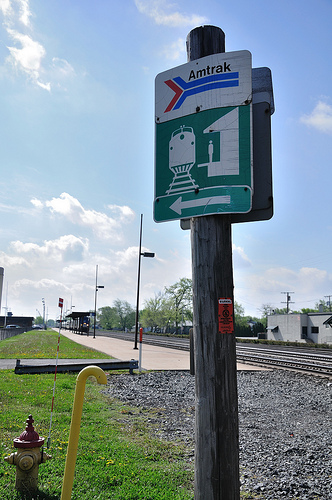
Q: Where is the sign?
A: On a post.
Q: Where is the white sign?
A: On a post.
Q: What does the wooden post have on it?
A: Signs.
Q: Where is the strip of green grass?
A: Near the sidewalk.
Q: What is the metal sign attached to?
A: The post.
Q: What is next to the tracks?
A: A gravel-covered area.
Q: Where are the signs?
A: Near the tracks.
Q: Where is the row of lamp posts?
A: Near the tracks.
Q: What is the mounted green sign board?
A: A train platform indicator.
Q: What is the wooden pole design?
A: An Amtrak sign.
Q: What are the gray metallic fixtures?
A: Train tracks.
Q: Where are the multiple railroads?
A: On tracks.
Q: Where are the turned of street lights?
A: Along the tracks.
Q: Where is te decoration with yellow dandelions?
A: On the small grassy field.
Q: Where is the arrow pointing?
A: To the left.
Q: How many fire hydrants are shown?
A: 1.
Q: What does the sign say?
A: Amtrak.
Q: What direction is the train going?
A: Right.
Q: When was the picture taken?
A: During the day.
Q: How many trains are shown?
A: 1.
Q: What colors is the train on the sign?
A: White and green.